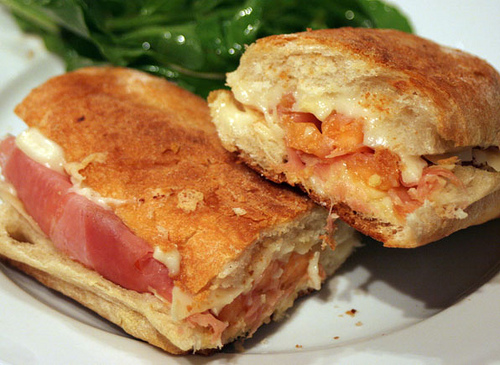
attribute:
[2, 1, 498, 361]
plate — white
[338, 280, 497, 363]
plate — white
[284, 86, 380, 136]
cheese — melted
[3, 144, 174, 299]
ham — pink, fatty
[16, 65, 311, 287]
crust — brown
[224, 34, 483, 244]
sandwich — brown and white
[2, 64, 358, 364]
sandwich half — toasted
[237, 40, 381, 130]
dough — white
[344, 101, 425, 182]
cheese — white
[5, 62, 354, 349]
sandwich roll — brown, golden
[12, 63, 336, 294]
bread — brown, flaky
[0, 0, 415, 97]
leaves — green, moist 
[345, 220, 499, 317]
shadow — dark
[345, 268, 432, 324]
border — light 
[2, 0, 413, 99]
green vegetable — shiny